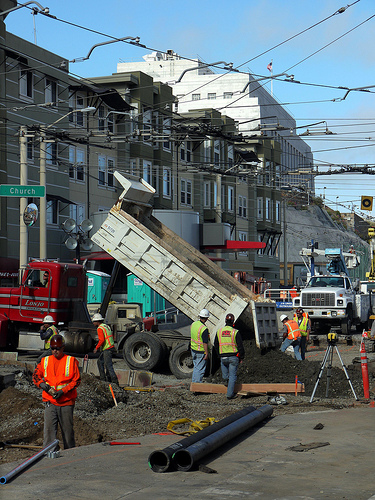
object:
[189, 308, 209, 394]
worker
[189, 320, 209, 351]
vest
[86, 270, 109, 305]
port-a-potty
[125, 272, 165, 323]
port-a-potty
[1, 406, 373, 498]
ground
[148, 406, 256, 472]
sewer pipe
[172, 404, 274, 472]
sewer pipe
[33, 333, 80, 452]
man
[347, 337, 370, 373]
safety cone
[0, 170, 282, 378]
dump truck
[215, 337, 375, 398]
dirt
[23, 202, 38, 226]
mirror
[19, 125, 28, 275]
pole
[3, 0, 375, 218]
sky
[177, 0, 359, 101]
wires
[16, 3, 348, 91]
cables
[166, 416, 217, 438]
strap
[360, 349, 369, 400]
pole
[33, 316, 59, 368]
man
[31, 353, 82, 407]
safety clothes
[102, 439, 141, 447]
tool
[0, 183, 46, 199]
sign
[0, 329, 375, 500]
street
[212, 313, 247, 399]
person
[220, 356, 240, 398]
jeans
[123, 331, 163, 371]
tire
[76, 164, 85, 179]
windows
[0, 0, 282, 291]
building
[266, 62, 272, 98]
flag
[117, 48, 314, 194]
building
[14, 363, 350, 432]
gravel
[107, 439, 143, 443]
handle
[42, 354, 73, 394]
vest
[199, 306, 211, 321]
safety helmet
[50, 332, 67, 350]
helmet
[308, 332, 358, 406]
equipment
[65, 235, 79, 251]
lights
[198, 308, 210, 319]
helmet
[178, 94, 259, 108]
roof